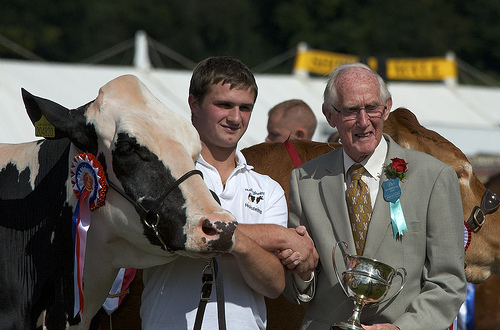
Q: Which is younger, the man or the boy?
A: The boy is younger than the man.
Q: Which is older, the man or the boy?
A: The man is older than the boy.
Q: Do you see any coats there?
A: Yes, there is a coat.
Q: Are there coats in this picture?
A: Yes, there is a coat.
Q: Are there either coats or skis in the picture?
A: Yes, there is a coat.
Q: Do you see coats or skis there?
A: Yes, there is a coat.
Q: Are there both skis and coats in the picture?
A: No, there is a coat but no skis.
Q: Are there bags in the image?
A: No, there are no bags.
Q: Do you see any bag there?
A: No, there are no bags.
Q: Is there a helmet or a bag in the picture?
A: No, there are no bags or helmets.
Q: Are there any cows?
A: Yes, there is a cow.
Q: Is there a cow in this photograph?
A: Yes, there is a cow.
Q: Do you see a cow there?
A: Yes, there is a cow.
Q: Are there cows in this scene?
A: Yes, there is a cow.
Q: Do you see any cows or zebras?
A: Yes, there is a cow.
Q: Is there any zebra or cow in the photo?
A: Yes, there is a cow.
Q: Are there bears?
A: No, there are no bears.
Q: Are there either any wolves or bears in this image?
A: No, there are no bears or wolves.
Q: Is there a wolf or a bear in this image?
A: No, there are no bears or wolves.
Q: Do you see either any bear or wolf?
A: No, there are no bears or wolves.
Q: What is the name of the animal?
A: The animal is a cow.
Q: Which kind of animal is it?
A: The animal is a cow.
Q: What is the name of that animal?
A: That is a cow.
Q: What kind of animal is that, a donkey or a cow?
A: That is a cow.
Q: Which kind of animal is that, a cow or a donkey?
A: That is a cow.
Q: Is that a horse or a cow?
A: That is a cow.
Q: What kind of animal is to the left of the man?
A: The animal is a cow.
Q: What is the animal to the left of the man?
A: The animal is a cow.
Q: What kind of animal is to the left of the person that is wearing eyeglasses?
A: The animal is a cow.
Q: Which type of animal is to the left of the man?
A: The animal is a cow.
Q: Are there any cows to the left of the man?
A: Yes, there is a cow to the left of the man.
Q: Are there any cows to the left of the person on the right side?
A: Yes, there is a cow to the left of the man.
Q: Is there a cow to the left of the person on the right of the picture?
A: Yes, there is a cow to the left of the man.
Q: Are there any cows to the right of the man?
A: No, the cow is to the left of the man.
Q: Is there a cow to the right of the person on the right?
A: No, the cow is to the left of the man.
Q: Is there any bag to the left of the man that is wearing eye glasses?
A: No, there is a cow to the left of the man.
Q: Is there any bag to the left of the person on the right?
A: No, there is a cow to the left of the man.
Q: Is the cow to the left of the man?
A: Yes, the cow is to the left of the man.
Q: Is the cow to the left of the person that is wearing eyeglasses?
A: Yes, the cow is to the left of the man.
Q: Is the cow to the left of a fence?
A: No, the cow is to the left of the man.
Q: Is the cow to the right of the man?
A: No, the cow is to the left of the man.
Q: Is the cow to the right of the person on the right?
A: No, the cow is to the left of the man.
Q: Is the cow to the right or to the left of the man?
A: The cow is to the left of the man.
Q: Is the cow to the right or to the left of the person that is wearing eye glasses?
A: The cow is to the left of the man.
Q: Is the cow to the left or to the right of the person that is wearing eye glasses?
A: The cow is to the left of the man.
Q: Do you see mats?
A: No, there are no mats.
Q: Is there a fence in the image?
A: No, there are no fences.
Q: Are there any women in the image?
A: No, there are no women.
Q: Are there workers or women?
A: No, there are no women or workers.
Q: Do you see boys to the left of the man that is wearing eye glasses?
A: Yes, there is a boy to the left of the man.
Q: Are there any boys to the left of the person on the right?
A: Yes, there is a boy to the left of the man.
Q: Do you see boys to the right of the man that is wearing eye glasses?
A: No, the boy is to the left of the man.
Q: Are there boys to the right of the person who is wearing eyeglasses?
A: No, the boy is to the left of the man.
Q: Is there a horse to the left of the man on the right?
A: No, there is a boy to the left of the man.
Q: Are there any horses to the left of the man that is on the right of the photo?
A: No, there is a boy to the left of the man.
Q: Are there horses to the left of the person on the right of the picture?
A: No, there is a boy to the left of the man.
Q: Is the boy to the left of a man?
A: Yes, the boy is to the left of a man.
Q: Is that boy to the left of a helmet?
A: No, the boy is to the left of a man.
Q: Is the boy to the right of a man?
A: No, the boy is to the left of a man.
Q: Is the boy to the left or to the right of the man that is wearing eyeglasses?
A: The boy is to the left of the man.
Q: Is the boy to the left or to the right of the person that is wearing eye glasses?
A: The boy is to the left of the man.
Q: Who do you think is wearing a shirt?
A: The boy is wearing a shirt.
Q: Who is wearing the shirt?
A: The boy is wearing a shirt.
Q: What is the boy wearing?
A: The boy is wearing a shirt.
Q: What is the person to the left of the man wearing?
A: The boy is wearing a shirt.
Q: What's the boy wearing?
A: The boy is wearing a shirt.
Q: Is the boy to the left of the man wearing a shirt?
A: Yes, the boy is wearing a shirt.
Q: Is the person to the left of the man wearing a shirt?
A: Yes, the boy is wearing a shirt.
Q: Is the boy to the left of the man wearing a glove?
A: No, the boy is wearing a shirt.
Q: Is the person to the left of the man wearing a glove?
A: No, the boy is wearing a shirt.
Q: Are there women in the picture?
A: No, there are no women.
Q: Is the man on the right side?
A: Yes, the man is on the right of the image.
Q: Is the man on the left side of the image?
A: No, the man is on the right of the image.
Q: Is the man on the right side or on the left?
A: The man is on the right of the image.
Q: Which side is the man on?
A: The man is on the right of the image.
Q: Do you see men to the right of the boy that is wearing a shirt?
A: Yes, there is a man to the right of the boy.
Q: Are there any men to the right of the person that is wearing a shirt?
A: Yes, there is a man to the right of the boy.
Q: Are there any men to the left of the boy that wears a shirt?
A: No, the man is to the right of the boy.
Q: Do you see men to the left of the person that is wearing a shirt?
A: No, the man is to the right of the boy.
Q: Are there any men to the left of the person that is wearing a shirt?
A: No, the man is to the right of the boy.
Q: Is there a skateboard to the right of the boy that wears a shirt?
A: No, there is a man to the right of the boy.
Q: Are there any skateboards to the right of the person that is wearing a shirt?
A: No, there is a man to the right of the boy.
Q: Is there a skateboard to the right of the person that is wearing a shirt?
A: No, there is a man to the right of the boy.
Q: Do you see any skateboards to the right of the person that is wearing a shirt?
A: No, there is a man to the right of the boy.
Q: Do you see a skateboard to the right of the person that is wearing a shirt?
A: No, there is a man to the right of the boy.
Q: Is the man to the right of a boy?
A: Yes, the man is to the right of a boy.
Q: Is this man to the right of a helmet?
A: No, the man is to the right of a boy.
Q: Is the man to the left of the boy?
A: No, the man is to the right of the boy.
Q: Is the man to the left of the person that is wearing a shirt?
A: No, the man is to the right of the boy.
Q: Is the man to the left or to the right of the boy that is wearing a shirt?
A: The man is to the right of the boy.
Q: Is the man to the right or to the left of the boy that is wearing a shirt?
A: The man is to the right of the boy.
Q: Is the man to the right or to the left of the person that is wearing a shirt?
A: The man is to the right of the boy.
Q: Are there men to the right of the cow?
A: Yes, there is a man to the right of the cow.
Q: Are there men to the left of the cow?
A: No, the man is to the right of the cow.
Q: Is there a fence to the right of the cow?
A: No, there is a man to the right of the cow.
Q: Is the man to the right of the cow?
A: Yes, the man is to the right of the cow.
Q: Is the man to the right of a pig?
A: No, the man is to the right of the cow.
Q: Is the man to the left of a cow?
A: No, the man is to the right of a cow.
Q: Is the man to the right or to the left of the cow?
A: The man is to the right of the cow.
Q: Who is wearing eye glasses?
A: The man is wearing eye glasses.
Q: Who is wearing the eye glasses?
A: The man is wearing eye glasses.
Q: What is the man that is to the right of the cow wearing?
A: The man is wearing eyeglasses.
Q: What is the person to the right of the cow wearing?
A: The man is wearing eyeglasses.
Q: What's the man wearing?
A: The man is wearing eyeglasses.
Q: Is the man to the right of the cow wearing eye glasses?
A: Yes, the man is wearing eye glasses.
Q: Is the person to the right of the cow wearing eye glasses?
A: Yes, the man is wearing eye glasses.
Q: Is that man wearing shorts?
A: No, the man is wearing eye glasses.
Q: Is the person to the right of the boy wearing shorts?
A: No, the man is wearing eye glasses.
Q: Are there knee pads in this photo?
A: No, there are no knee pads.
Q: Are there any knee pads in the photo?
A: No, there are no knee pads.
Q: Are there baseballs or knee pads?
A: No, there are no knee pads or baseballs.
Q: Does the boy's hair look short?
A: Yes, the hair is short.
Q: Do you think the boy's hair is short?
A: Yes, the hair is short.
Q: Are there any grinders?
A: No, there are no grinders.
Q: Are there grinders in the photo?
A: No, there are no grinders.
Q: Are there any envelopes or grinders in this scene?
A: No, there are no grinders or envelopes.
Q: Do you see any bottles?
A: No, there are no bottles.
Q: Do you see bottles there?
A: No, there are no bottles.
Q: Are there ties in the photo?
A: Yes, there is a tie.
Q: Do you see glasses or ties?
A: Yes, there is a tie.